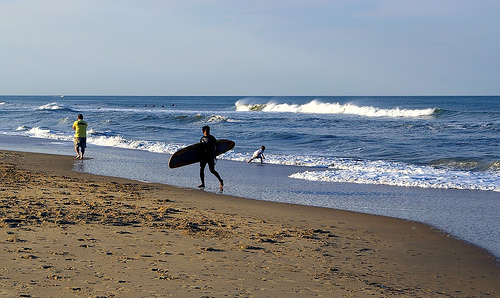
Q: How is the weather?
A: It is cloudy.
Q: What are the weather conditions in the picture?
A: It is cloudy.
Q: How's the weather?
A: It is cloudy.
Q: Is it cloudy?
A: Yes, it is cloudy.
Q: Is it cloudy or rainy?
A: It is cloudy.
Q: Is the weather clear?
A: No, it is cloudy.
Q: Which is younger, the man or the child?
A: The child is younger than the man.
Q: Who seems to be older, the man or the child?
A: The man is older than the child.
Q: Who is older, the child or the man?
A: The man is older than the child.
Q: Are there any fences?
A: No, there are no fences.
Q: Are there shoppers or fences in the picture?
A: No, there are no fences or shoppers.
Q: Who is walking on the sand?
A: The man is walking on the sand.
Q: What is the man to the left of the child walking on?
A: The man is walking on the sand.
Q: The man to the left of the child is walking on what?
A: The man is walking on the sand.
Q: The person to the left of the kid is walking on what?
A: The man is walking on the sand.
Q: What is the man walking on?
A: The man is walking on the sand.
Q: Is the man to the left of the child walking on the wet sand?
A: Yes, the man is walking on the sand.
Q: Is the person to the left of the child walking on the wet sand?
A: Yes, the man is walking on the sand.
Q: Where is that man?
A: The man is on the sand.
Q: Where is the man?
A: The man is on the sand.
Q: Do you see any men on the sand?
A: Yes, there is a man on the sand.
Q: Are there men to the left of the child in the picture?
A: Yes, there is a man to the left of the child.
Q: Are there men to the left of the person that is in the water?
A: Yes, there is a man to the left of the child.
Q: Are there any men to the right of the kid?
A: No, the man is to the left of the kid.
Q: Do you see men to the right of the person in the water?
A: No, the man is to the left of the kid.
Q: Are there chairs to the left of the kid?
A: No, there is a man to the left of the kid.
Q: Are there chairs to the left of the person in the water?
A: No, there is a man to the left of the kid.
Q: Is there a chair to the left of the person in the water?
A: No, there is a man to the left of the kid.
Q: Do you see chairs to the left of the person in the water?
A: No, there is a man to the left of the kid.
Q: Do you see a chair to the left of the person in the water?
A: No, there is a man to the left of the kid.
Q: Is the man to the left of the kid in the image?
A: Yes, the man is to the left of the kid.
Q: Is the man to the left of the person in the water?
A: Yes, the man is to the left of the kid.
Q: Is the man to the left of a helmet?
A: No, the man is to the left of the kid.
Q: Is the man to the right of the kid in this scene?
A: No, the man is to the left of the kid.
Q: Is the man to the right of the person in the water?
A: No, the man is to the left of the kid.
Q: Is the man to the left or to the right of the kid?
A: The man is to the left of the kid.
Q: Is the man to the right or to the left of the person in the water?
A: The man is to the left of the kid.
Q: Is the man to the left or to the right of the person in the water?
A: The man is to the left of the kid.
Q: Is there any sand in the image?
A: Yes, there is sand.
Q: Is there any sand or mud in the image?
A: Yes, there is sand.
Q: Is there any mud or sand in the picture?
A: Yes, there is sand.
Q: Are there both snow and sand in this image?
A: No, there is sand but no snow.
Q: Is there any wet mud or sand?
A: Yes, there is wet sand.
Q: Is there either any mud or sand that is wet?
A: Yes, the sand is wet.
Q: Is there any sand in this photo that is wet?
A: Yes, there is wet sand.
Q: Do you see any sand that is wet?
A: Yes, there is sand that is wet.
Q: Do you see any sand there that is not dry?
A: Yes, there is wet sand.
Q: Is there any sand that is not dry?
A: Yes, there is wet sand.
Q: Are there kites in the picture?
A: No, there are no kites.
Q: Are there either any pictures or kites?
A: No, there are no kites or pictures.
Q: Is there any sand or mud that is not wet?
A: No, there is sand but it is wet.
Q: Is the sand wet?
A: Yes, the sand is wet.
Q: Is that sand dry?
A: No, the sand is wet.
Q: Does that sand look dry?
A: No, the sand is wet.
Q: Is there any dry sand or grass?
A: No, there is sand but it is wet.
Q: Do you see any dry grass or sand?
A: No, there is sand but it is wet.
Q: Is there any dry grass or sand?
A: No, there is sand but it is wet.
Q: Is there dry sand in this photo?
A: No, there is sand but it is wet.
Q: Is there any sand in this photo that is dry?
A: No, there is sand but it is wet.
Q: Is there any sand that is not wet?
A: No, there is sand but it is wet.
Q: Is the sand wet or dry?
A: The sand is wet.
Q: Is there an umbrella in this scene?
A: No, there are no umbrellas.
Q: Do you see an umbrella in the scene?
A: No, there are no umbrellas.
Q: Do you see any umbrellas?
A: No, there are no umbrellas.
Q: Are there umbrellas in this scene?
A: No, there are no umbrellas.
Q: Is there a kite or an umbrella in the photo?
A: No, there are no umbrellas or kites.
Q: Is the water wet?
A: Yes, the water is wet.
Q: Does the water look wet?
A: Yes, the water is wet.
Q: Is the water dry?
A: No, the water is wet.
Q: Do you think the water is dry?
A: No, the water is wet.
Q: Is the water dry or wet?
A: The water is wet.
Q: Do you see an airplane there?
A: No, there are no airplanes.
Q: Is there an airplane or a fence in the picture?
A: No, there are no airplanes or fences.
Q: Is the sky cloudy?
A: Yes, the sky is cloudy.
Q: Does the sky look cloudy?
A: Yes, the sky is cloudy.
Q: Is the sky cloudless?
A: No, the sky is cloudy.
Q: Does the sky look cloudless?
A: No, the sky is cloudy.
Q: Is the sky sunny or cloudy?
A: The sky is cloudy.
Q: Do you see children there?
A: Yes, there is a child.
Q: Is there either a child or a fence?
A: Yes, there is a child.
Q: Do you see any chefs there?
A: No, there are no chefs.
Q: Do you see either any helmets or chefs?
A: No, there are no chefs or helmets.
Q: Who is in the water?
A: The kid is in the water.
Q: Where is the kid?
A: The kid is in the water.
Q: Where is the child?
A: The kid is in the water.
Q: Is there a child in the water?
A: Yes, there is a child in the water.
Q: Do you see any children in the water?
A: Yes, there is a child in the water.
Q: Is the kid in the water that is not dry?
A: Yes, the kid is in the water.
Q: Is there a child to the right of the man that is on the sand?
A: Yes, there is a child to the right of the man.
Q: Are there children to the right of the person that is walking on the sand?
A: Yes, there is a child to the right of the man.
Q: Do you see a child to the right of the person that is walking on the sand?
A: Yes, there is a child to the right of the man.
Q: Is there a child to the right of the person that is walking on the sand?
A: Yes, there is a child to the right of the man.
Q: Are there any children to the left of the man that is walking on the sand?
A: No, the child is to the right of the man.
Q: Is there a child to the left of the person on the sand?
A: No, the child is to the right of the man.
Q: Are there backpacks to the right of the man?
A: No, there is a child to the right of the man.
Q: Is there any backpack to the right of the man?
A: No, there is a child to the right of the man.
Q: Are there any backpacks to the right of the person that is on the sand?
A: No, there is a child to the right of the man.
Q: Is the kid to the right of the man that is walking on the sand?
A: Yes, the kid is to the right of the man.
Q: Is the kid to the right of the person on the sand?
A: Yes, the kid is to the right of the man.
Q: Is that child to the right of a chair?
A: No, the child is to the right of the man.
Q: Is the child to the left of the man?
A: No, the child is to the right of the man.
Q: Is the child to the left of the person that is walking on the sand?
A: No, the child is to the right of the man.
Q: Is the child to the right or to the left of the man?
A: The child is to the right of the man.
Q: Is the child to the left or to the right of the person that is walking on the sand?
A: The child is to the right of the man.